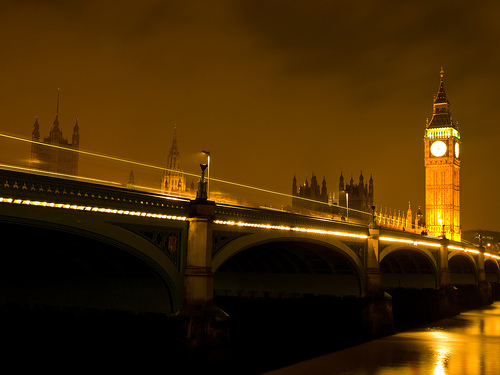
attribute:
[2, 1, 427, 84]
sky — cloudy, night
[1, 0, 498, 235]
sky — dark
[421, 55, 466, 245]
tower — illumnated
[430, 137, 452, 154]
clock — illuminated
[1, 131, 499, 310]
bridge — large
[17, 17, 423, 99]
sky — overcast , evening 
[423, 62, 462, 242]
tower — lit, brightly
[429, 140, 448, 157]
clock — lit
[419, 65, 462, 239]
tower — tall, luminous